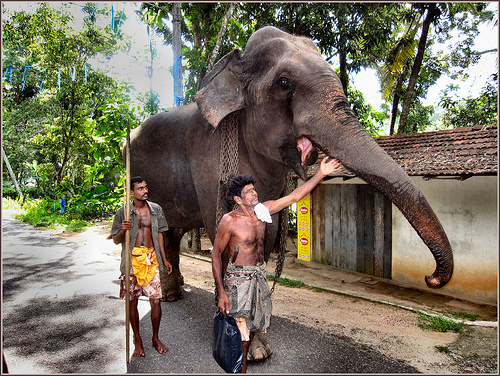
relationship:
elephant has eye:
[112, 1, 379, 261] [276, 66, 299, 91]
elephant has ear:
[112, 1, 379, 261] [172, 63, 247, 138]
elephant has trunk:
[112, 1, 379, 261] [307, 107, 460, 261]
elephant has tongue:
[112, 1, 379, 261] [292, 132, 313, 158]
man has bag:
[193, 155, 315, 375] [192, 302, 243, 372]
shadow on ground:
[32, 297, 71, 336] [27, 246, 111, 365]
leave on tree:
[47, 60, 80, 95] [0, 57, 102, 205]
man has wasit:
[193, 155, 315, 375] [222, 236, 282, 274]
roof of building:
[413, 140, 457, 159] [341, 107, 491, 298]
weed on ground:
[8, 166, 124, 253] [27, 246, 111, 365]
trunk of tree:
[307, 107, 460, 261] [0, 57, 102, 205]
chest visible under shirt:
[233, 220, 272, 274] [246, 200, 274, 221]